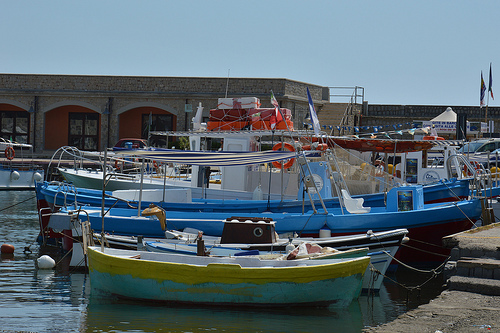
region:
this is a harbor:
[140, 176, 258, 326]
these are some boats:
[188, 129, 263, 264]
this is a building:
[88, 73, 130, 191]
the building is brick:
[24, 41, 167, 142]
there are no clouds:
[196, 41, 258, 85]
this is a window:
[53, 117, 98, 144]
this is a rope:
[397, 250, 454, 301]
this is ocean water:
[13, 297, 43, 317]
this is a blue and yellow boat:
[253, 277, 280, 289]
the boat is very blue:
[270, 113, 321, 244]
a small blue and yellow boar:
[83, 222, 367, 307]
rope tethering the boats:
[384, 251, 431, 285]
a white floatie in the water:
[32, 251, 64, 278]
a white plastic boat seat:
[339, 185, 370, 216]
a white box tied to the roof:
[211, 92, 265, 109]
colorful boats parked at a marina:
[52, 112, 471, 315]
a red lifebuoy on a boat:
[3, 143, 22, 159]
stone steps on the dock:
[449, 241, 499, 297]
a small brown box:
[224, 208, 266, 243]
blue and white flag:
[304, 85, 324, 127]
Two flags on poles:
[469, 61, 499, 106]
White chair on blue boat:
[337, 187, 369, 214]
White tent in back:
[427, 105, 457, 135]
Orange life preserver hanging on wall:
[267, 140, 297, 170]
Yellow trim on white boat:
[84, 247, 374, 285]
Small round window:
[252, 225, 265, 238]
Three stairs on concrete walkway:
[444, 243, 499, 293]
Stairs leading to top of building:
[316, 100, 356, 128]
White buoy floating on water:
[35, 253, 56, 273]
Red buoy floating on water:
[0, 239, 17, 261]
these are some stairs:
[427, 218, 494, 331]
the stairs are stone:
[447, 220, 492, 327]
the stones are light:
[403, 276, 473, 308]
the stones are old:
[455, 260, 471, 332]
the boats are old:
[215, 305, 275, 319]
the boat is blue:
[306, 183, 358, 251]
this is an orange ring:
[231, 99, 294, 176]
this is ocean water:
[67, 281, 109, 321]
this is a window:
[50, 98, 122, 178]